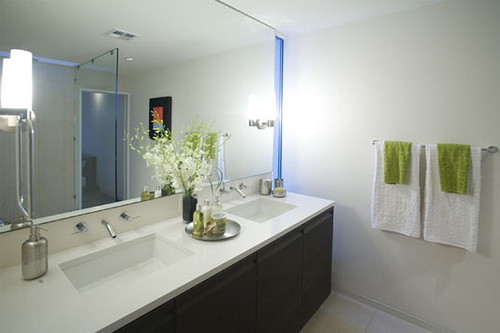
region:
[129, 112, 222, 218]
white flowers in a vase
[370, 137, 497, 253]
two white towels on a towel rack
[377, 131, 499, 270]
two green wash cloths on top towels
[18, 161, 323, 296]
two sinks in the bathroom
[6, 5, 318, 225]
large mirror above bathroom sinks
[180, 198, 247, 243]
silver tray with items on it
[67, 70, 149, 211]
reflection of a door in the mirror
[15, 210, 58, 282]
a silver soap dispenser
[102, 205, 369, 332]
brown cabinets under bathroom sinks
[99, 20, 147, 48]
ceiling vent in the bathroom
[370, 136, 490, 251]
white and green towels on a towel rack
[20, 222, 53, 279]
metallic soap dispenser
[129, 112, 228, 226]
plant with white flowers in a black vase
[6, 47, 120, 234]
reflection of glass shower door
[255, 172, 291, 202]
toiletries in metal containers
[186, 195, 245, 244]
toiletries on a round plate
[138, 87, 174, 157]
black framed painting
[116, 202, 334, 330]
dark brown cabinets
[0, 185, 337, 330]
bathroom counter top with two sinks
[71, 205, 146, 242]
faucets built in a wall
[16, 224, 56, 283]
silver soap dispenser on the left side of the sink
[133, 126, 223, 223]
white and green bouquet in between the two sinks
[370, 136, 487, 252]
two towels hanging on drying rack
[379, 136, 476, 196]
two small olive towels laying over bigger white towels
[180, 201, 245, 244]
circular tray holding beauty products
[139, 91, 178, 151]
artwork hanging on wall that is reflected in the mirror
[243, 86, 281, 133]
bright light hanging on mirror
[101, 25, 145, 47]
air vent on ceiling reflected in mirror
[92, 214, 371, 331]
dark brown cabinets with no handles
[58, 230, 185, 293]
rectangular sink, white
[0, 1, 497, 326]
this is a bathrom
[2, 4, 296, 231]
bathroom has a mirror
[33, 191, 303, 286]
counter has two sinks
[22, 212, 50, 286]
soap sitting on counter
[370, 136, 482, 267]
two white hand towels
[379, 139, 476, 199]
two green wash cloths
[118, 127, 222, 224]
flowers on bathroom counter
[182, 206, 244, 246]
tray of lotion on bathroom counter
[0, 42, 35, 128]
reflection of bathroom light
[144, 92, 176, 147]
reflection of black picture on wall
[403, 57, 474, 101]
this is the wall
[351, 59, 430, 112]
the wall is white in color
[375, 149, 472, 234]
these are some towels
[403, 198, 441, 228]
the towels are white in color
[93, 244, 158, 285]
this is a sink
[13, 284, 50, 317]
the base is made of tiles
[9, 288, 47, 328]
the area is white in color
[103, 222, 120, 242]
the tap is metallic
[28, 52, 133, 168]
this is a mirror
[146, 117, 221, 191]
these are some flowers